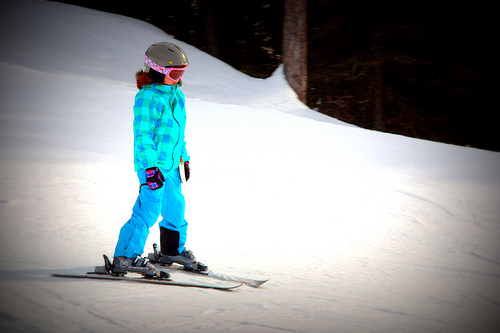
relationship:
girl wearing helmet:
[51, 36, 267, 304] [130, 36, 194, 76]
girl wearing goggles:
[51, 36, 267, 304] [142, 58, 183, 80]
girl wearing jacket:
[51, 36, 267, 304] [132, 82, 196, 166]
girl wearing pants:
[51, 36, 267, 304] [125, 167, 196, 252]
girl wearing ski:
[51, 36, 267, 304] [53, 266, 235, 294]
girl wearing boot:
[51, 36, 267, 304] [113, 250, 146, 266]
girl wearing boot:
[51, 36, 267, 304] [161, 222, 192, 255]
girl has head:
[51, 36, 267, 304] [137, 46, 194, 84]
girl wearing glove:
[51, 36, 267, 304] [145, 165, 170, 190]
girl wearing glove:
[51, 36, 267, 304] [182, 153, 197, 180]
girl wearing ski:
[51, 36, 267, 304] [168, 255, 270, 288]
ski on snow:
[53, 266, 235, 294] [3, 35, 473, 333]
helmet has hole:
[130, 36, 194, 76] [165, 46, 176, 58]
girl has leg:
[51, 36, 267, 304] [118, 175, 160, 258]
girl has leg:
[51, 36, 267, 304] [158, 173, 192, 258]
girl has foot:
[51, 36, 267, 304] [112, 232, 161, 279]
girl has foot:
[51, 36, 267, 304] [155, 233, 208, 270]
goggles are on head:
[142, 58, 183, 80] [137, 46, 194, 84]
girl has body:
[51, 36, 267, 304] [114, 78, 199, 268]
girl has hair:
[51, 36, 267, 304] [127, 59, 161, 91]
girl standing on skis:
[51, 36, 267, 304] [66, 242, 264, 302]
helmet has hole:
[130, 36, 194, 76] [173, 43, 184, 59]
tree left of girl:
[277, 0, 316, 99] [51, 36, 267, 304]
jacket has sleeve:
[132, 82, 196, 166] [129, 93, 162, 165]